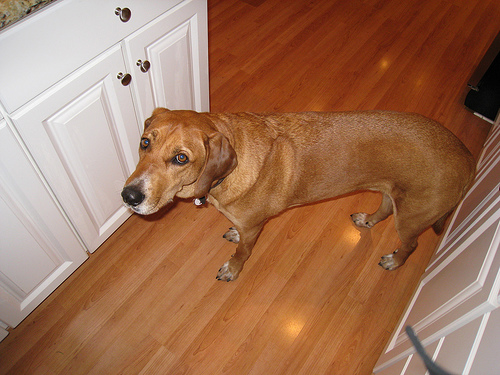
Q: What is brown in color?
A: The dog.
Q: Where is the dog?
A: On the floor.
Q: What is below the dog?
A: The floor.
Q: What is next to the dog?
A: Cabinet.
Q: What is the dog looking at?
A: The camera.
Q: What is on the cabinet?
A: Knobs.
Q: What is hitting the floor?
A: Light.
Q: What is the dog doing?
A: Looking at camera.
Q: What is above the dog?
A: A drawer.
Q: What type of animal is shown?
A: Dog.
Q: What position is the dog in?
A: Standing.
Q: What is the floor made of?
A: Hardwood.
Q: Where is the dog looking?
A: At the camera.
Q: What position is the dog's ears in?
A: Laying down.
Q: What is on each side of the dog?
A: Cabinets.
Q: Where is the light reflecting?
A: Floor.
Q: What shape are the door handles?
A: Round.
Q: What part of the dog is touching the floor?
A: Feet.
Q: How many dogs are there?
A: One.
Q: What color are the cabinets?
A: White.